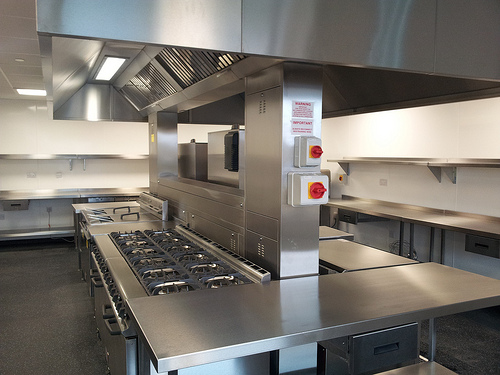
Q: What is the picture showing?
A: It is showing a kitchen.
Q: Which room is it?
A: It is a kitchen.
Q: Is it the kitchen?
A: Yes, it is the kitchen.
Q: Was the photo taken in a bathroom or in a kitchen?
A: It was taken at a kitchen.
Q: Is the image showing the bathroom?
A: No, the picture is showing the kitchen.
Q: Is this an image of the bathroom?
A: No, the picture is showing the kitchen.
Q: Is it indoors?
A: Yes, it is indoors.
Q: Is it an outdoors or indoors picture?
A: It is indoors.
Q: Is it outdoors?
A: No, it is indoors.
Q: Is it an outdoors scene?
A: No, it is indoors.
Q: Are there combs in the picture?
A: No, there are no combs.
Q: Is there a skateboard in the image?
A: No, there are no skateboards.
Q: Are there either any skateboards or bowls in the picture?
A: No, there are no skateboards or bowls.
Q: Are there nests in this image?
A: No, there are no nests.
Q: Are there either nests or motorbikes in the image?
A: No, there are no nests or motorbikes.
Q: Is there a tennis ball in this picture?
A: No, there are no tennis balls.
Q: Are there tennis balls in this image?
A: No, there are no tennis balls.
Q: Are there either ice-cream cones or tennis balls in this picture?
A: No, there are no tennis balls or ice-cream cones.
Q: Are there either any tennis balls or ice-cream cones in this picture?
A: No, there are no tennis balls or ice-cream cones.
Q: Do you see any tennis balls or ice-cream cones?
A: No, there are no tennis balls or ice-cream cones.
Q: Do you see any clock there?
A: No, there are no clocks.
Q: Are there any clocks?
A: No, there are no clocks.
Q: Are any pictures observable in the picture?
A: No, there are no pictures.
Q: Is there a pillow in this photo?
A: No, there are no pillows.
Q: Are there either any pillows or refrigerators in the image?
A: No, there are no pillows or refrigerators.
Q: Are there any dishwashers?
A: No, there are no dishwashers.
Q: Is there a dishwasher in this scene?
A: No, there are no dishwashers.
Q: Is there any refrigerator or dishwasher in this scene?
A: No, there are no dishwashers or refrigerators.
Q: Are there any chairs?
A: No, there are no chairs.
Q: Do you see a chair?
A: No, there are no chairs.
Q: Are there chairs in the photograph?
A: No, there are no chairs.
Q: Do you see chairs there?
A: No, there are no chairs.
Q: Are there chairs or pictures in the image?
A: No, there are no chairs or pictures.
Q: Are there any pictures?
A: No, there are no pictures.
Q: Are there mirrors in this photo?
A: No, there are no mirrors.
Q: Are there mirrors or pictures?
A: No, there are no mirrors or pictures.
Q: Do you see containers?
A: No, there are no containers.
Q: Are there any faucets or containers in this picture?
A: No, there are no containers or faucets.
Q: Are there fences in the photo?
A: No, there are no fences.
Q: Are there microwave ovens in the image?
A: No, there are no microwave ovens.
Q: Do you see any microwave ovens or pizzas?
A: No, there are no microwave ovens or pizzas.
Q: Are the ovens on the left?
A: Yes, the ovens are on the left of the image.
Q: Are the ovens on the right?
A: No, the ovens are on the left of the image.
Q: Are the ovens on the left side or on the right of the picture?
A: The ovens are on the left of the image.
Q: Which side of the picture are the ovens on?
A: The ovens are on the left of the image.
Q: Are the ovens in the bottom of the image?
A: Yes, the ovens are in the bottom of the image.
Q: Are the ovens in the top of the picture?
A: No, the ovens are in the bottom of the image.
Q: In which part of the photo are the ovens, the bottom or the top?
A: The ovens are in the bottom of the image.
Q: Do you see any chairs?
A: No, there are no chairs.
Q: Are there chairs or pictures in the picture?
A: No, there are no chairs or pictures.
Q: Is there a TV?
A: No, there are no televisions.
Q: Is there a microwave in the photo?
A: No, there are no microwaves.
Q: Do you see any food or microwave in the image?
A: No, there are no microwaves or food.